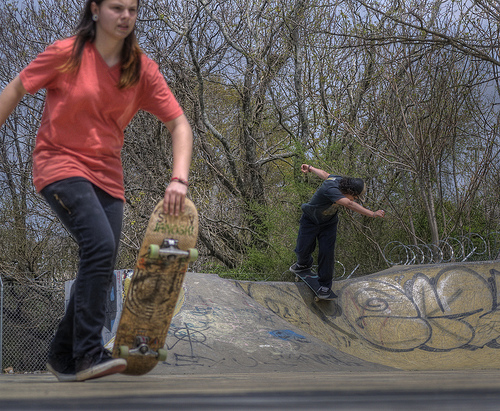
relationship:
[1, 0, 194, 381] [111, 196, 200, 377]
girl lifting skateboard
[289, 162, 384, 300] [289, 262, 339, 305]
man riding skateboard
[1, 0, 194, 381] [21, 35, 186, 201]
girl wearing shirt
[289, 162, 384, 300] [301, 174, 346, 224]
man wearing shirt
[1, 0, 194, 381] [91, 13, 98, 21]
girl wearing earring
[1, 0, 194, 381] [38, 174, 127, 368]
girl wearing pants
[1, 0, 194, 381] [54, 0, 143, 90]
girl has hair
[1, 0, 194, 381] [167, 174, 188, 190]
girl wearing bracelet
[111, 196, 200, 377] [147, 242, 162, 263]
skateboard has wheel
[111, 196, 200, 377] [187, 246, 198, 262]
skateboard has wheel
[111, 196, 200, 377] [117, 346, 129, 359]
skateboard has wheel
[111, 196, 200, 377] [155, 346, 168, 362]
skateboard has wheel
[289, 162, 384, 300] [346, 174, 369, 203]
man wearing hat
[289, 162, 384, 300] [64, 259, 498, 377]
man on wall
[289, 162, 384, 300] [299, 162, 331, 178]
man has arm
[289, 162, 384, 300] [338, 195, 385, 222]
man has arm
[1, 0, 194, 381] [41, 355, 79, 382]
girl wearing shoe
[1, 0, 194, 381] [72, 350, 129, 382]
girl wearing shoe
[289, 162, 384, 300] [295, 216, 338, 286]
man wearing jeans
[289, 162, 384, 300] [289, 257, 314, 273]
man has shoe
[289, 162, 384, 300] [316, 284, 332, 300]
man has shoe